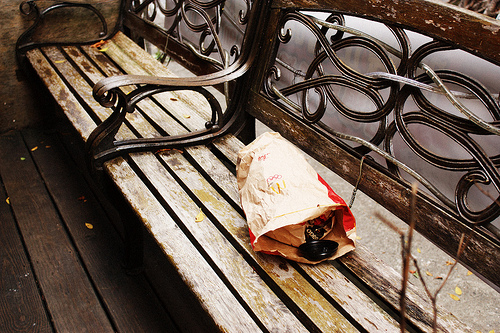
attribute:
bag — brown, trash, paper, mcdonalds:
[229, 128, 351, 257]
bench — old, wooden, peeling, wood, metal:
[94, 0, 498, 332]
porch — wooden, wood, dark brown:
[3, 121, 209, 332]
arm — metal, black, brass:
[91, 57, 241, 166]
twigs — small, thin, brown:
[322, 125, 476, 332]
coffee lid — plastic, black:
[294, 236, 334, 261]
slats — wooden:
[127, 130, 404, 332]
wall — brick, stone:
[1, 5, 112, 143]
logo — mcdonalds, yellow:
[266, 169, 298, 202]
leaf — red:
[93, 37, 108, 57]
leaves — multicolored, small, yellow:
[7, 133, 99, 234]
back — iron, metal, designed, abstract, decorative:
[254, 1, 499, 267]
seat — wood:
[117, 141, 455, 332]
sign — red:
[314, 177, 358, 233]